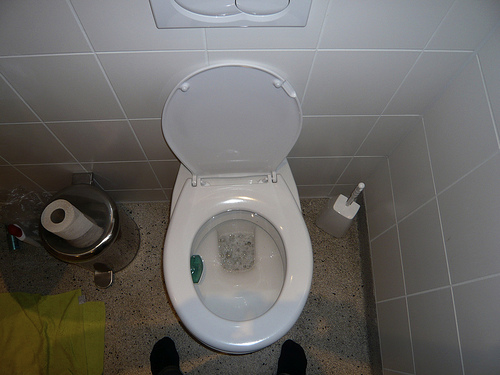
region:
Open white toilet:
[157, 63, 317, 358]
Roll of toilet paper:
[39, 198, 91, 240]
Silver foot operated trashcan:
[37, 167, 141, 290]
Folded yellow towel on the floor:
[0, 286, 110, 372]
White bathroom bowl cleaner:
[316, 180, 366, 240]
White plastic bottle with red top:
[7, 219, 42, 251]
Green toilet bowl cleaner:
[188, 248, 205, 286]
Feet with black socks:
[148, 332, 310, 374]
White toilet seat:
[160, 173, 315, 352]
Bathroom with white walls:
[0, 0, 498, 374]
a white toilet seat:
[47, 56, 461, 353]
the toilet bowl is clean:
[161, 181, 312, 329]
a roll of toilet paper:
[34, 186, 90, 246]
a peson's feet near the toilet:
[127, 320, 310, 373]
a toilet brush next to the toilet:
[293, 167, 403, 262]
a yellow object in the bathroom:
[7, 282, 122, 374]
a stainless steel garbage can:
[42, 181, 157, 299]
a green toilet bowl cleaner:
[187, 254, 207, 284]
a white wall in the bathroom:
[367, 109, 495, 374]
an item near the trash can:
[2, 199, 45, 268]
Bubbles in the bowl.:
[205, 215, 262, 282]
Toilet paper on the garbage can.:
[41, 200, 92, 249]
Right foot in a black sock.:
[142, 333, 187, 373]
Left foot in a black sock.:
[270, 331, 328, 373]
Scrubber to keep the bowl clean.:
[320, 162, 377, 242]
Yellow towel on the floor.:
[17, 284, 108, 360]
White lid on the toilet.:
[164, 57, 313, 190]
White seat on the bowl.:
[161, 170, 316, 360]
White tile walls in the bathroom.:
[367, 98, 472, 337]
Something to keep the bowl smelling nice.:
[186, 245, 206, 287]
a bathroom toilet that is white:
[123, 108, 425, 374]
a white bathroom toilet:
[126, 150, 350, 373]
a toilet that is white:
[104, 87, 371, 374]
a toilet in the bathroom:
[160, 140, 300, 351]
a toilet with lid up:
[107, 58, 289, 373]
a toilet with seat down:
[133, 100, 325, 373]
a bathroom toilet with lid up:
[171, 81, 371, 354]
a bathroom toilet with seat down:
[125, 71, 308, 374]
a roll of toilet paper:
[53, 177, 107, 258]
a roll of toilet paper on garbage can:
[47, 164, 102, 250]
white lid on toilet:
[119, 45, 297, 202]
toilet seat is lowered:
[170, 201, 296, 305]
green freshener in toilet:
[170, 246, 199, 283]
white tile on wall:
[369, 191, 485, 308]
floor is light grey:
[319, 266, 352, 349]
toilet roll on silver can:
[45, 205, 116, 265]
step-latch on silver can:
[75, 265, 110, 291]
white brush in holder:
[316, 181, 353, 237]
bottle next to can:
[5, 199, 44, 255]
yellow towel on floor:
[0, 298, 103, 363]